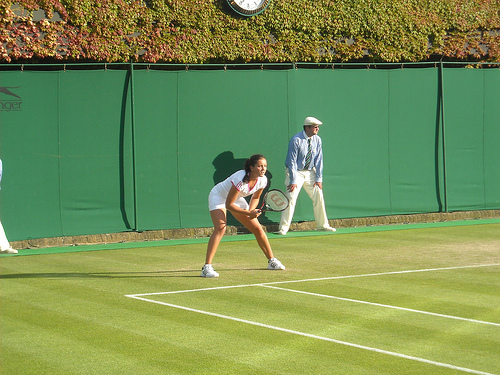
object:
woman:
[200, 153, 287, 278]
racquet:
[257, 188, 291, 213]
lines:
[127, 295, 498, 373]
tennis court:
[2, 257, 499, 374]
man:
[275, 115, 337, 235]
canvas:
[4, 69, 498, 234]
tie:
[303, 138, 313, 171]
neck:
[305, 133, 311, 136]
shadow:
[212, 150, 231, 171]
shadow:
[0, 269, 206, 278]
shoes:
[200, 264, 220, 277]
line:
[123, 263, 498, 298]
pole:
[440, 63, 448, 212]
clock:
[226, 0, 270, 17]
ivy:
[2, 4, 496, 56]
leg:
[201, 197, 228, 277]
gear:
[208, 168, 290, 225]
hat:
[301, 116, 325, 126]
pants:
[277, 167, 330, 231]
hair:
[246, 155, 255, 166]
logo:
[1, 86, 25, 112]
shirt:
[284, 130, 323, 184]